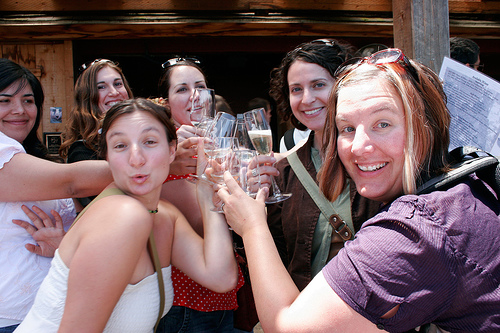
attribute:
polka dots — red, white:
[174, 266, 254, 314]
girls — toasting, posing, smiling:
[14, 55, 449, 264]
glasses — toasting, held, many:
[187, 90, 313, 235]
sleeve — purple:
[323, 217, 464, 326]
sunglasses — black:
[157, 55, 216, 75]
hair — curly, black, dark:
[264, 45, 357, 109]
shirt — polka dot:
[146, 191, 244, 321]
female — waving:
[5, 55, 116, 310]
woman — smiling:
[275, 33, 349, 251]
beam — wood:
[392, 8, 455, 76]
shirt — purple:
[336, 190, 494, 322]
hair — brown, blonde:
[75, 73, 102, 135]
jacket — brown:
[266, 148, 428, 303]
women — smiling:
[276, 49, 479, 228]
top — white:
[42, 235, 202, 328]